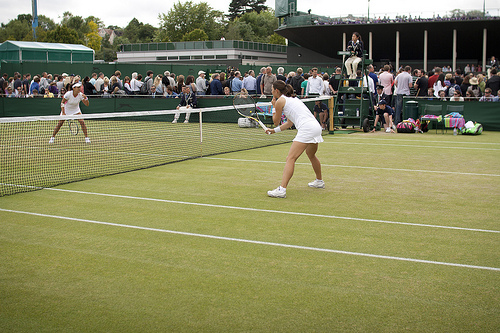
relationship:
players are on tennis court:
[47, 80, 326, 198] [1, 120, 497, 273]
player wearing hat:
[46, 83, 92, 145] [71, 83, 82, 92]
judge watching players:
[340, 32, 365, 81] [47, 80, 326, 198]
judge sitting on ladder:
[340, 32, 365, 81] [326, 50, 377, 131]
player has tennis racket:
[234, 79, 325, 197] [232, 91, 268, 136]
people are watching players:
[5, 65, 499, 101] [47, 80, 326, 198]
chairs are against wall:
[417, 104, 467, 134] [1, 97, 498, 131]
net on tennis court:
[1, 96, 334, 197] [1, 120, 497, 273]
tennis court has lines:
[1, 120, 497, 273] [1, 122, 494, 272]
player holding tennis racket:
[46, 83, 92, 145] [66, 120, 81, 135]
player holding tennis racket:
[234, 79, 325, 197] [232, 91, 268, 136]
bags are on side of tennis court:
[235, 119, 482, 134] [1, 120, 497, 273]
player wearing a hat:
[46, 83, 92, 145] [71, 83, 82, 92]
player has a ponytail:
[234, 79, 325, 197] [281, 83, 297, 100]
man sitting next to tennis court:
[169, 86, 198, 124] [1, 120, 497, 273]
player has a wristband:
[234, 79, 325, 197] [273, 126, 282, 134]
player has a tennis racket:
[46, 83, 92, 145] [66, 120, 81, 135]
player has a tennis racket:
[234, 79, 325, 197] [232, 91, 268, 136]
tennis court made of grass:
[1, 120, 497, 273] [2, 119, 498, 330]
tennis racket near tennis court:
[66, 120, 81, 135] [1, 120, 497, 273]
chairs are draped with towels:
[417, 104, 467, 134] [424, 114, 462, 128]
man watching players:
[169, 86, 198, 124] [47, 80, 326, 198]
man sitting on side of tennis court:
[169, 86, 198, 124] [1, 120, 497, 273]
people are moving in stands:
[5, 65, 499, 101] [6, 0, 496, 98]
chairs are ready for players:
[417, 104, 467, 134] [47, 80, 326, 198]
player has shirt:
[46, 83, 92, 145] [60, 90, 87, 110]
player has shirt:
[234, 79, 325, 197] [278, 95, 317, 128]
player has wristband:
[234, 79, 325, 197] [273, 126, 282, 134]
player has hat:
[46, 83, 92, 145] [71, 83, 82, 92]